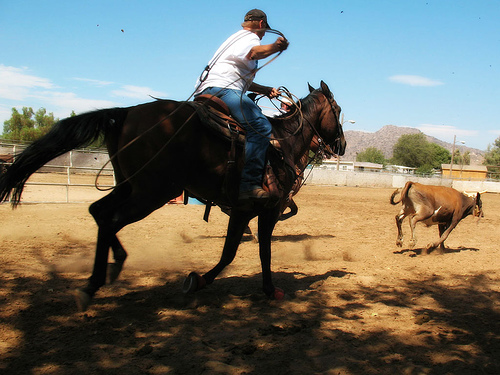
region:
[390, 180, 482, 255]
a small brown cow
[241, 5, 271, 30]
the man has a black cap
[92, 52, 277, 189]
a rope lasso on the horse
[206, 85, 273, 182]
the man is wearing blue jeans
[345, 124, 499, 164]
a brown rocky hill in the background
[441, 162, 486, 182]
a small yellow shed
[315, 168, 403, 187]
a wood fence along the field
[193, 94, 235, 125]
a brown leather saddle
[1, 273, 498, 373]
shadows showing on the dirt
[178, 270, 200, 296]
the horses metal horse shoe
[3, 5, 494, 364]
A man on a horse chasing a cow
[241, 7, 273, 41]
The man's head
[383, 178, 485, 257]
A brown cow running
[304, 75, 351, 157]
The horse's head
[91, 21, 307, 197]
Rope in the man's hand to lasso the cow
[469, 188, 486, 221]
The cow's head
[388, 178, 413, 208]
The cow's tail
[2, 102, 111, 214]
The horse's tail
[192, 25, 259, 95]
The man on the horse's white t shirt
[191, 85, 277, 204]
The man on the horse's blue pants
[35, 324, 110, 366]
Small patch of brown dirt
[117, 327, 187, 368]
Small patch of brown dirt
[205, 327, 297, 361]
Small patch of brown dirt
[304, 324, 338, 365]
Small patch of brown dirt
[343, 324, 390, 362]
Small patch of brown dirt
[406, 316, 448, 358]
Small patch of brown dirt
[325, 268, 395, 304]
Small patch of brown dirt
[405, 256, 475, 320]
Small patch of brown dirt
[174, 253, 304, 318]
Small patch of brown dirt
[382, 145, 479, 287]
Cow running in the dirt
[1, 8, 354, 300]
a man riding on a brown horse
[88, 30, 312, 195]
a lasso in the man's right hand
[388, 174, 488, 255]
a cow running away from the men on horseback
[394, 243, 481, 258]
the shadow of the cow being cast in the dirt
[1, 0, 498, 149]
a blue sky with a few clouds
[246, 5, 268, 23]
a baseball cap on the man's head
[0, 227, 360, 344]
the shadow of the horses on the ground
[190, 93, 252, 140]
a saddle on the brown horse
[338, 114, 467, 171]
a couple of street lights in the distance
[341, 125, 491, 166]
a large hill in the distance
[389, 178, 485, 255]
a brown cow that is running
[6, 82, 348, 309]
a dark brown horse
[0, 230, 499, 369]
shadows on the ground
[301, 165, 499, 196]
a white wooden fence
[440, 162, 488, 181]
a brown building with a gray roof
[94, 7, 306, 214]
the man has a lasso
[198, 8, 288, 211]
than man is wearing blue jeans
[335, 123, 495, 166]
mountain is the background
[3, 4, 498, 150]
blue sky with white clouds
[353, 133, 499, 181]
building beside the trees